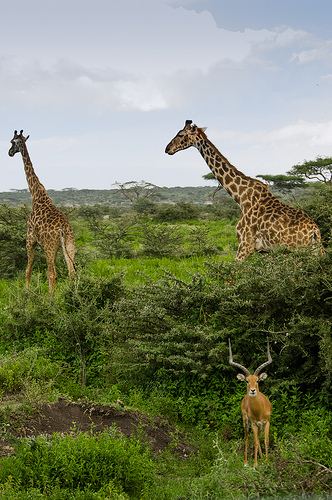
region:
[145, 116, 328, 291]
this is a giraffe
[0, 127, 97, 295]
this is a giraffe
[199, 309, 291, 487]
this is an impala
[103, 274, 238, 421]
a shrub of trees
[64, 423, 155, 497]
a shrub of trees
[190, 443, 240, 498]
a shrub of trees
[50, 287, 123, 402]
a shrub of trees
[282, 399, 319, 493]
a shrub of trees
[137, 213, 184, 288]
a shrub of trees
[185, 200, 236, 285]
a shrub of trees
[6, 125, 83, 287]
tall brown giraffe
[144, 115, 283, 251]
tall spotted giraffe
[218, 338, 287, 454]
antelope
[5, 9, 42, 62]
white clouds in blue sky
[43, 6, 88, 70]
white clouds in blue sky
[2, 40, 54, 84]
white clouds in blue sky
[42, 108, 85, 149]
white clouds in blue sky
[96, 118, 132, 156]
white clouds in blue sky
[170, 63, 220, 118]
white clouds in blue sky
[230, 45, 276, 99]
white clouds in blue sky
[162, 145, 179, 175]
Giraffe has brown nose.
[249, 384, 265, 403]
Animal has black nose.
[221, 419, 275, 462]
Animal has 4 brown legs.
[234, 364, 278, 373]
Large brown horns on animals head.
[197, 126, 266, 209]
Brown hair down back of giraffe's neck.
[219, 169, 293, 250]
Giraffe is brown and tan.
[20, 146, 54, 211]
Giraffe has long neck.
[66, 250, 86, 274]
Black hair on end of giraffe's tail.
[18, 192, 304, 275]
2 giraffes standing in grassy area.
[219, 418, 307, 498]
Animal standing near greenery.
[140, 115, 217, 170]
head of the giraffe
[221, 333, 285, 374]
antlers on the animal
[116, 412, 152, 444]
brown dirt on ground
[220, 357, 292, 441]
brown and white animal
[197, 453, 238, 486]
grass on the ground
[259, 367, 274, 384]
ear of the animal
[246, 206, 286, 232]
brown spots on animal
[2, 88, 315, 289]
two different giraffes in photo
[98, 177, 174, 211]
trees in the distance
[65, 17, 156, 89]
sky above the land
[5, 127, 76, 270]
giraffe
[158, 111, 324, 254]
brown spotted giraffe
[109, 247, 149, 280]
tall green and yellow grass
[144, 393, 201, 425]
tall green and yellow grass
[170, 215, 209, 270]
tall green and yellow grass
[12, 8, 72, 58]
white clouds in blue sky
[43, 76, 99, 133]
white clouds in blue sky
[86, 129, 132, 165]
white clouds in blue sky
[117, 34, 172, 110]
white clouds in blue sky